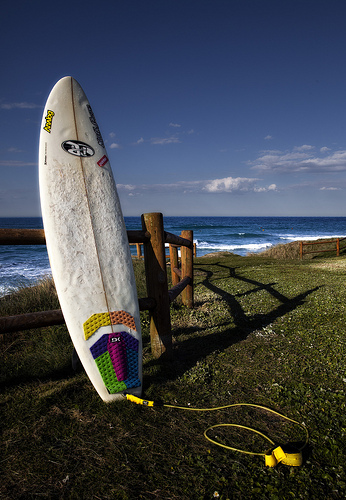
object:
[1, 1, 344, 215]
sky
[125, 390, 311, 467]
strap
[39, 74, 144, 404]
surfboard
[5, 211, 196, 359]
fence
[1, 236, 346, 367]
beach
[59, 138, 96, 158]
pattern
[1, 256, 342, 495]
grass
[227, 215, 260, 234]
water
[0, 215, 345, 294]
ocean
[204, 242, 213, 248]
whitecaps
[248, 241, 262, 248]
waves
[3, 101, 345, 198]
clouds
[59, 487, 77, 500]
flowers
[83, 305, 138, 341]
patches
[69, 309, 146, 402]
end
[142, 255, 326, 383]
shadows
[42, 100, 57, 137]
stickers